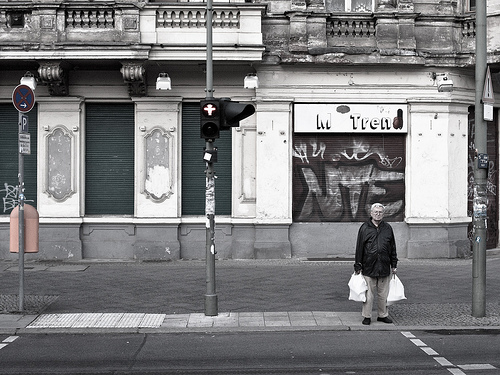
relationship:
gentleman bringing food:
[354, 203, 398, 325] [384, 272, 407, 304]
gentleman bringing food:
[354, 203, 398, 325] [345, 272, 365, 304]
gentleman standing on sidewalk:
[354, 203, 398, 325] [11, 248, 498, 322]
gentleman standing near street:
[354, 203, 398, 325] [2, 334, 499, 374]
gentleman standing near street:
[354, 203, 398, 325] [97, 236, 448, 371]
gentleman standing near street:
[354, 203, 398, 325] [2, 328, 495, 370]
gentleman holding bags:
[354, 203, 398, 325] [334, 270, 419, 317]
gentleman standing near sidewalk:
[354, 203, 398, 325] [11, 248, 498, 322]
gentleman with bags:
[354, 203, 398, 325] [344, 270, 366, 307]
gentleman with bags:
[354, 203, 398, 325] [346, 267, 370, 307]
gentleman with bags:
[354, 203, 398, 325] [384, 267, 407, 307]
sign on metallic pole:
[20, 114, 29, 131] [17, 81, 25, 311]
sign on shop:
[287, 104, 409, 134] [1, 100, 477, 237]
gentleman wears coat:
[354, 203, 398, 325] [354, 220, 396, 280]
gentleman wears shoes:
[354, 203, 398, 325] [352, 312, 393, 327]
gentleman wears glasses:
[354, 203, 398, 325] [369, 209, 385, 215]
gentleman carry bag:
[354, 203, 398, 325] [347, 271, 368, 302]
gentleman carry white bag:
[354, 203, 398, 325] [346, 293, 369, 303]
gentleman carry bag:
[354, 203, 398, 325] [386, 273, 406, 306]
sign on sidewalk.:
[12, 85, 35, 113] [48, 208, 499, 340]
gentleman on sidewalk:
[354, 203, 398, 325] [7, 299, 497, 331]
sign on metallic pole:
[15, 128, 32, 155] [14, 81, 26, 311]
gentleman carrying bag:
[354, 203, 398, 325] [386, 268, 407, 308]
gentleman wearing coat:
[354, 203, 398, 325] [353, 216, 399, 283]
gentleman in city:
[354, 203, 398, 325] [4, 5, 498, 370]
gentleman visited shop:
[354, 203, 398, 325] [1, 100, 476, 258]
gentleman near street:
[347, 201, 408, 326] [2, 328, 495, 370]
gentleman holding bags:
[354, 203, 398, 325] [339, 267, 411, 303]